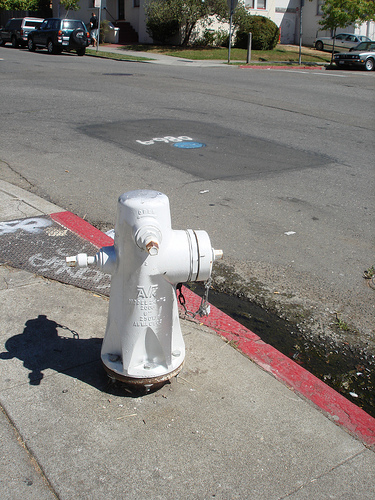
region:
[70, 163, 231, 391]
A white fire hydrant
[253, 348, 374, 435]
the red on the curb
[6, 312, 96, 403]
The shadow of the fire hydrant on the sidewalk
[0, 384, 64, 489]
The line in the sidewalk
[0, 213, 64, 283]
White spray paint on the metal grate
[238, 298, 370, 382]
A puddle next to the red marked curb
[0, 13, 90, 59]
Cars parked on the roadside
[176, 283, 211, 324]
A chain hanging from the fire hydrant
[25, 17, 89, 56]
A green jeep on the side of the road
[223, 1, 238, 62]
The back of a stop sign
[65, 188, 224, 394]
white fire hydrant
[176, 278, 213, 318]
metal chain on fire hydrant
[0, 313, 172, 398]
shadow of fire hydrant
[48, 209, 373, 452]
red line on curb under fire hydrant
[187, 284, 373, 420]
puddle next to fire hydrant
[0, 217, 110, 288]
white graffiti behind fire hydrant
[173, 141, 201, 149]
blue cover in street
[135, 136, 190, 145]
white marking on road next to cover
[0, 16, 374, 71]
cars parked by street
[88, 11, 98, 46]
person walking by cars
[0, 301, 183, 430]
The shadow of a fire hydrant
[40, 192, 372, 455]
a red line is painted on the edge of the sidewalk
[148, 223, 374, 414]
a puddle on the side of the road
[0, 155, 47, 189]
a crack in the street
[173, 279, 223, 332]
a silver chain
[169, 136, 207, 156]
a blue man hole cover in the street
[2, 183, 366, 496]
the sidewalk has cracks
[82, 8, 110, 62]
a person is walking on the sidewalk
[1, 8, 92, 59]
2 SUV's are parked by the curb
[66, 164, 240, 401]
This is a picture of a white fire hydrant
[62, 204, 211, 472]
This is a hydrant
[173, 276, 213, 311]
This is a hydrant chain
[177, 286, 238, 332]
The chain is silver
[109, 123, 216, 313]
The hydrant is made of metal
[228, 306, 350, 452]
This is red paint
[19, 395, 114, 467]
This is a sidewalk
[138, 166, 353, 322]
This is a street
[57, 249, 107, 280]
This is a knob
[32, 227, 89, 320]
This is painted words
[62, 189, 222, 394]
fire hydrant on side of road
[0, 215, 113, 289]
white graffiti on sidewalk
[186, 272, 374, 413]
puddle of water on the road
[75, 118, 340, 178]
dark patch in the middle of the road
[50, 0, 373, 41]
houses in the distance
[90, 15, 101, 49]
man on the sidewalk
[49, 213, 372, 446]
red area of sidewalk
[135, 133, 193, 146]
white writing in the middle of the road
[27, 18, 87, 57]
green car parked on the side of the road